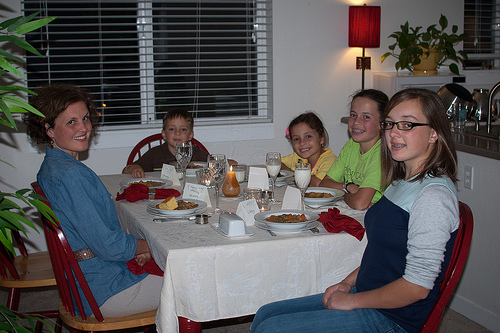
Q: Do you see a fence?
A: No, there are no fences.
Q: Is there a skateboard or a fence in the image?
A: No, there are no fences or skateboards.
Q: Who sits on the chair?
A: The boy sits on the chair.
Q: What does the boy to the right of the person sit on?
A: The boy sits on the chair.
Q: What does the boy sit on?
A: The boy sits on the chair.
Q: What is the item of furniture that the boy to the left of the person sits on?
A: The piece of furniture is a chair.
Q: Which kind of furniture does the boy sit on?
A: The boy sits on the chair.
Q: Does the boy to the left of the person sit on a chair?
A: Yes, the boy sits on a chair.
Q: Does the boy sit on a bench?
A: No, the boy sits on a chair.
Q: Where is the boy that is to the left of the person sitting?
A: The boy is sitting at the dining table.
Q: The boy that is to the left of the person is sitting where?
A: The boy is sitting at the dining table.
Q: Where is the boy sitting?
A: The boy is sitting at the dining table.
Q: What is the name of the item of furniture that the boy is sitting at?
A: The piece of furniture is a dining table.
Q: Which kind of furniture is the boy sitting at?
A: The boy is sitting at the dining table.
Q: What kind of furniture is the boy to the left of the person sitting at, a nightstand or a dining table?
A: The boy is sitting at a dining table.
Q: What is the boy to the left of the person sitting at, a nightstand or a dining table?
A: The boy is sitting at a dining table.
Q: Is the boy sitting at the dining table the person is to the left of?
A: Yes, the boy is sitting at the dining table.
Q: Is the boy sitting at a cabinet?
A: No, the boy is sitting at the dining table.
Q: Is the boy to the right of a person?
A: No, the boy is to the left of a person.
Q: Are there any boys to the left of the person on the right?
A: Yes, there is a boy to the left of the person.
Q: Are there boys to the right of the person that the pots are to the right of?
A: No, the boy is to the left of the person.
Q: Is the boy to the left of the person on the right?
A: Yes, the boy is to the left of the person.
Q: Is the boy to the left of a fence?
A: No, the boy is to the left of the person.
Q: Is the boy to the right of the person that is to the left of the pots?
A: No, the boy is to the left of the person.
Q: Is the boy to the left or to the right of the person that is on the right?
A: The boy is to the left of the person.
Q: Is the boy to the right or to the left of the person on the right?
A: The boy is to the left of the person.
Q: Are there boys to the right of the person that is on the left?
A: Yes, there is a boy to the right of the person.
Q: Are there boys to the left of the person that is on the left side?
A: No, the boy is to the right of the person.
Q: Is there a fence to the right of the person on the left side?
A: No, there is a boy to the right of the person.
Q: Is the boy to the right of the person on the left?
A: Yes, the boy is to the right of the person.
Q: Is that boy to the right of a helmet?
A: No, the boy is to the right of the person.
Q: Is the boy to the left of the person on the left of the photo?
A: No, the boy is to the right of the person.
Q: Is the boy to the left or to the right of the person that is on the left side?
A: The boy is to the right of the person.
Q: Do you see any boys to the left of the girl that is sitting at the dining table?
A: Yes, there is a boy to the left of the girl.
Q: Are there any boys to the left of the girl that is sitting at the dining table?
A: Yes, there is a boy to the left of the girl.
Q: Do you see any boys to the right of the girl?
A: No, the boy is to the left of the girl.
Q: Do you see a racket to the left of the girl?
A: No, there is a boy to the left of the girl.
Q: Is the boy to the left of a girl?
A: Yes, the boy is to the left of a girl.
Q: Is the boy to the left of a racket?
A: No, the boy is to the left of a girl.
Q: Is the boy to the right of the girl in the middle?
A: No, the boy is to the left of the girl.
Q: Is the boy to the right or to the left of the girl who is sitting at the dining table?
A: The boy is to the left of the girl.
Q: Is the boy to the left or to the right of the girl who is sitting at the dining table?
A: The boy is to the left of the girl.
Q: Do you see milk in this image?
A: Yes, there is milk.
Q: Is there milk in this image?
A: Yes, there is milk.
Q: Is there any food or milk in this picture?
A: Yes, there is milk.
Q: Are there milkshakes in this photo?
A: No, there are no milkshakes.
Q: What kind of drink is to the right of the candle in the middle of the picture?
A: The drink is milk.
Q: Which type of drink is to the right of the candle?
A: The drink is milk.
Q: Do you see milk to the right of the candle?
A: Yes, there is milk to the right of the candle.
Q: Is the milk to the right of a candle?
A: Yes, the milk is to the right of a candle.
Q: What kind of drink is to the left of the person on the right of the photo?
A: The drink is milk.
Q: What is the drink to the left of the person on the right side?
A: The drink is milk.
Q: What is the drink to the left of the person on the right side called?
A: The drink is milk.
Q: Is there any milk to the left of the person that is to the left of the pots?
A: Yes, there is milk to the left of the person.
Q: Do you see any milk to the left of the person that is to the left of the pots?
A: Yes, there is milk to the left of the person.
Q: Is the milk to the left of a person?
A: Yes, the milk is to the left of a person.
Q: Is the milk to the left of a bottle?
A: No, the milk is to the left of a person.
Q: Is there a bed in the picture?
A: No, there are no beds.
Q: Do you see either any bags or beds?
A: No, there are no beds or bags.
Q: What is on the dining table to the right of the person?
A: The card is on the dining table.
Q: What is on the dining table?
A: The card is on the dining table.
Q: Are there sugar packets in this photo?
A: No, there are no sugar packets.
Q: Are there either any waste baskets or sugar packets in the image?
A: No, there are no sugar packets or waste baskets.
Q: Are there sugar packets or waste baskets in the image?
A: No, there are no sugar packets or waste baskets.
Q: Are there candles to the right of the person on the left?
A: Yes, there is a candle to the right of the person.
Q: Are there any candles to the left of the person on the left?
A: No, the candle is to the right of the person.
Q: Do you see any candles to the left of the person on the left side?
A: No, the candle is to the right of the person.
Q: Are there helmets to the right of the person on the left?
A: No, there is a candle to the right of the person.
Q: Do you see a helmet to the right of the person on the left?
A: No, there is a candle to the right of the person.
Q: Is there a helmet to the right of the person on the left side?
A: No, there is a candle to the right of the person.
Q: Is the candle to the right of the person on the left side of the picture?
A: Yes, the candle is to the right of the person.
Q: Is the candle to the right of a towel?
A: No, the candle is to the right of the person.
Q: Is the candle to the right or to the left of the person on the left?
A: The candle is to the right of the person.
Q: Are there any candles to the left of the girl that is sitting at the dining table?
A: Yes, there is a candle to the left of the girl.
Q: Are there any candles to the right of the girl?
A: No, the candle is to the left of the girl.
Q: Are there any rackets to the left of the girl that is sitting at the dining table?
A: No, there is a candle to the left of the girl.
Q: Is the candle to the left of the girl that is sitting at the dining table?
A: Yes, the candle is to the left of the girl.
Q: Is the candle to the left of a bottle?
A: No, the candle is to the left of the girl.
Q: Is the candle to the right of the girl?
A: No, the candle is to the left of the girl.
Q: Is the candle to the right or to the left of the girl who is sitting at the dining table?
A: The candle is to the left of the girl.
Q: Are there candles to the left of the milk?
A: Yes, there is a candle to the left of the milk.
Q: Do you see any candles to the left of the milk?
A: Yes, there is a candle to the left of the milk.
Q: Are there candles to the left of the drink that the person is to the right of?
A: Yes, there is a candle to the left of the milk.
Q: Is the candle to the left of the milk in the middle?
A: Yes, the candle is to the left of the milk.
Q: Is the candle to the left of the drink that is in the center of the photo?
A: Yes, the candle is to the left of the milk.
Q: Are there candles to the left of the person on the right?
A: Yes, there is a candle to the left of the person.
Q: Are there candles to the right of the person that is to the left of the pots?
A: No, the candle is to the left of the person.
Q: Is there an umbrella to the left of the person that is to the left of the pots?
A: No, there is a candle to the left of the person.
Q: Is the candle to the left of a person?
A: Yes, the candle is to the left of a person.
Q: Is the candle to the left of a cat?
A: No, the candle is to the left of a person.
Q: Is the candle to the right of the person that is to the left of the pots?
A: No, the candle is to the left of the person.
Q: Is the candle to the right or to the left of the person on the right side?
A: The candle is to the left of the person.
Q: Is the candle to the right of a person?
A: No, the candle is to the left of a person.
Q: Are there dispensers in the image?
A: No, there are no dispensers.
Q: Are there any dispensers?
A: No, there are no dispensers.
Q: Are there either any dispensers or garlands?
A: No, there are no dispensers or garlands.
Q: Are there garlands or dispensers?
A: No, there are no dispensers or garlands.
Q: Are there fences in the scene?
A: No, there are no fences.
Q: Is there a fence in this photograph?
A: No, there are no fences.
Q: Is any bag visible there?
A: No, there are no bags.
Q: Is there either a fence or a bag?
A: No, there are no bags or fences.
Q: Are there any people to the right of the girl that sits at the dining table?
A: Yes, there is a person to the right of the girl.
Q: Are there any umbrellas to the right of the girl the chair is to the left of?
A: No, there is a person to the right of the girl.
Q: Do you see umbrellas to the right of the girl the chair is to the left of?
A: No, there is a person to the right of the girl.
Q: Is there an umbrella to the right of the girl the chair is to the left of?
A: No, there is a person to the right of the girl.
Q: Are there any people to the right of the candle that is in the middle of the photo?
A: Yes, there is a person to the right of the candle.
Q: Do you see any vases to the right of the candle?
A: No, there is a person to the right of the candle.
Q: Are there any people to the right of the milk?
A: Yes, there is a person to the right of the milk.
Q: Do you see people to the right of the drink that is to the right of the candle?
A: Yes, there is a person to the right of the milk.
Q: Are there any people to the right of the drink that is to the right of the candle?
A: Yes, there is a person to the right of the milk.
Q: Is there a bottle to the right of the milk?
A: No, there is a person to the right of the milk.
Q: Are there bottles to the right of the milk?
A: No, there is a person to the right of the milk.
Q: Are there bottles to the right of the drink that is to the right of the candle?
A: No, there is a person to the right of the milk.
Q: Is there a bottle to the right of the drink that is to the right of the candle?
A: No, there is a person to the right of the milk.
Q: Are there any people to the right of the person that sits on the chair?
A: Yes, there is a person to the right of the boy.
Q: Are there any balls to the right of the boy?
A: No, there is a person to the right of the boy.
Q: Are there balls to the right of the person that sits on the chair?
A: No, there is a person to the right of the boy.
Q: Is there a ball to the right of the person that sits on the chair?
A: No, there is a person to the right of the boy.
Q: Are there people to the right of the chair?
A: Yes, there is a person to the right of the chair.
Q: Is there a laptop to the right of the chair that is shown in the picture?
A: No, there is a person to the right of the chair.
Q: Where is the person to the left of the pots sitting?
A: The person is sitting at the dining table.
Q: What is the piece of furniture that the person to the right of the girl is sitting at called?
A: The piece of furniture is a dining table.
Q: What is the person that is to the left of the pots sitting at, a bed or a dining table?
A: The person is sitting at a dining table.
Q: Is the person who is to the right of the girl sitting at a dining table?
A: Yes, the person is sitting at a dining table.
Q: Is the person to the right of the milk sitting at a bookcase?
A: No, the person is sitting at a dining table.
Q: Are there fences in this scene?
A: No, there are no fences.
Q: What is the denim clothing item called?
A: The clothing item is a shirt.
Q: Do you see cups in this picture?
A: No, there are no cups.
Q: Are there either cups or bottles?
A: No, there are no cups or bottles.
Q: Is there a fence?
A: No, there are no fences.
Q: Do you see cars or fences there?
A: No, there are no fences or cars.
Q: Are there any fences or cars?
A: No, there are no fences or cars.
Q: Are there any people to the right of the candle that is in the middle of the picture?
A: Yes, there is a person to the right of the candle.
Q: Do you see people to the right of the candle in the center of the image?
A: Yes, there is a person to the right of the candle.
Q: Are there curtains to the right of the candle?
A: No, there is a person to the right of the candle.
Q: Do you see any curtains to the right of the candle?
A: No, there is a person to the right of the candle.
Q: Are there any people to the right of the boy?
A: Yes, there is a person to the right of the boy.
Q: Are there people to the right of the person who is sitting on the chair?
A: Yes, there is a person to the right of the boy.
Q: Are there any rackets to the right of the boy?
A: No, there is a person to the right of the boy.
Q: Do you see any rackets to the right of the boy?
A: No, there is a person to the right of the boy.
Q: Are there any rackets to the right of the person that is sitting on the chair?
A: No, there is a person to the right of the boy.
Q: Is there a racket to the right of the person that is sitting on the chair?
A: No, there is a person to the right of the boy.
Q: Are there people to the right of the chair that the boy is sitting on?
A: Yes, there is a person to the right of the chair.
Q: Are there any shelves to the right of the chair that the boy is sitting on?
A: No, there is a person to the right of the chair.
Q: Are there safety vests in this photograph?
A: No, there are no safety vests.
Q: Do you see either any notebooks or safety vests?
A: No, there are no safety vests or notebooks.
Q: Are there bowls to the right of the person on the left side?
A: Yes, there is a bowl to the right of the person.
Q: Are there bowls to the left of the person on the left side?
A: No, the bowl is to the right of the person.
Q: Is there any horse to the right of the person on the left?
A: No, there is a bowl to the right of the person.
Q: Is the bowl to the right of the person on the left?
A: Yes, the bowl is to the right of the person.